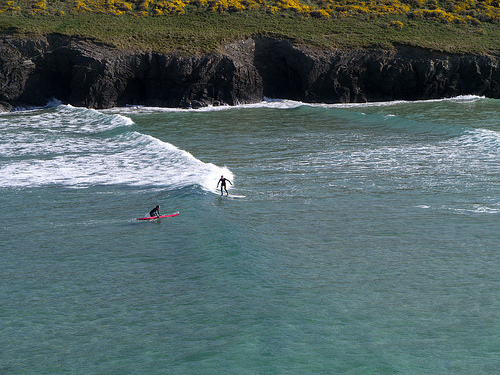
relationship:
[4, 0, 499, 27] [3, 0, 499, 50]
flowers on ground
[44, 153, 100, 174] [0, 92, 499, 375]
wave in ocean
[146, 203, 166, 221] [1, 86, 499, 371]
person in water